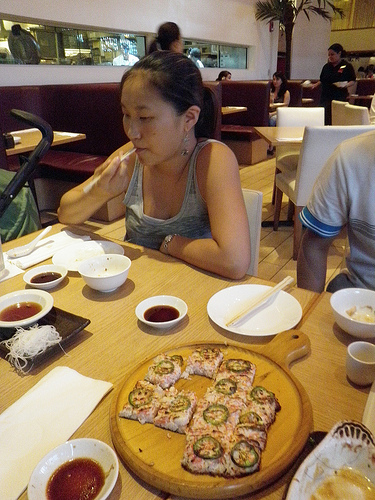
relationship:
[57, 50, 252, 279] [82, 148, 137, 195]
woman holding chopsticks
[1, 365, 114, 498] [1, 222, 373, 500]
napkin on top of table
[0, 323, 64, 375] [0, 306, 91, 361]
noodles are on top of plate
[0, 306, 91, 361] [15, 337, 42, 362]
plate has corner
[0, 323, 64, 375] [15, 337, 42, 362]
noodles are on top of corner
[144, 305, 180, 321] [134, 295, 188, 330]
sauce inside of bowl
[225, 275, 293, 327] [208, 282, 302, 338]
chopstick on top of plate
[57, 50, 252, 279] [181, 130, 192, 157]
woman wearing earrings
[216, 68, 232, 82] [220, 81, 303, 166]
person sitting in booth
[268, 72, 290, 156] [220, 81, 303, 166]
person sitting in booth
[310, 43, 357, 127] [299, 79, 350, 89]
person serving food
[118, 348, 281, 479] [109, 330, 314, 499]
pizza on top of board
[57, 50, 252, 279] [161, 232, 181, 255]
woman wearing watch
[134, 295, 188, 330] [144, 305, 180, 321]
bowl has sauce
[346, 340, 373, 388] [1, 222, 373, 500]
cup on top of table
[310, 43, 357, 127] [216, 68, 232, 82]
person near person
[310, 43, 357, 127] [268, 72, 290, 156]
person near person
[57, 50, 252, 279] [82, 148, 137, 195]
woman holding chopstick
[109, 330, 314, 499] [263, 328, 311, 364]
board has handle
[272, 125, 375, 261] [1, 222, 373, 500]
chair near table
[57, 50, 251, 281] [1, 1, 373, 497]
diner inside restaurant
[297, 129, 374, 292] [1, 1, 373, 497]
diner inside restaurant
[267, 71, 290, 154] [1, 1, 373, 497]
diner inside restaurant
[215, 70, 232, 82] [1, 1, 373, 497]
diner inside restaurant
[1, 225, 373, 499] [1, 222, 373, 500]
food spread on table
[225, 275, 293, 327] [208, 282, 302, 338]
chopstick across plate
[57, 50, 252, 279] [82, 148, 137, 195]
woman eating with chopstick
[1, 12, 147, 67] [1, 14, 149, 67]
kitchen behind window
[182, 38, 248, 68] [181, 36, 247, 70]
kitchen behind window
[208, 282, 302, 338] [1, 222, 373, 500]
plate on top of table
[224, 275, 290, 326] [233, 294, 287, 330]
chopstick has shadow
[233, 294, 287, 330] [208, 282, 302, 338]
shadow on top of plate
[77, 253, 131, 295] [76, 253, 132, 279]
bowl has edge